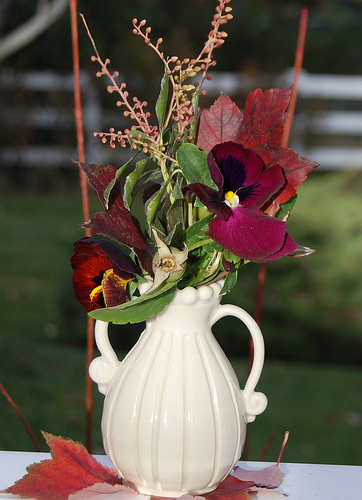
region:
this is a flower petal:
[29, 440, 97, 485]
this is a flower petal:
[237, 454, 300, 487]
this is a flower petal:
[81, 487, 124, 496]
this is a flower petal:
[218, 209, 288, 241]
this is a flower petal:
[206, 140, 261, 183]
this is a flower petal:
[251, 168, 288, 193]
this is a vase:
[93, 280, 260, 485]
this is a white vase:
[89, 282, 266, 493]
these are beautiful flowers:
[104, 113, 277, 286]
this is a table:
[4, 452, 13, 471]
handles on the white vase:
[81, 298, 279, 419]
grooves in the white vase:
[100, 325, 242, 487]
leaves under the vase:
[13, 434, 311, 498]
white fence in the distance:
[1, 65, 358, 196]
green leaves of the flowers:
[74, 71, 239, 321]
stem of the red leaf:
[274, 426, 292, 463]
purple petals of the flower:
[184, 138, 295, 260]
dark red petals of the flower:
[70, 231, 140, 308]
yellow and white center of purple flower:
[226, 190, 239, 207]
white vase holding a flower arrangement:
[68, 10, 297, 493]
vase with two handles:
[91, 284, 277, 493]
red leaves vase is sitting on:
[6, 424, 293, 499]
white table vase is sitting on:
[1, 447, 358, 499]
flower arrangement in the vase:
[60, 7, 323, 320]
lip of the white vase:
[133, 276, 222, 307]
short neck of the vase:
[138, 299, 216, 327]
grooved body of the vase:
[103, 325, 236, 494]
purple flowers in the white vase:
[186, 137, 299, 266]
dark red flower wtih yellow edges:
[64, 239, 131, 312]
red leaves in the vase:
[73, 88, 315, 269]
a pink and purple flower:
[188, 142, 287, 261]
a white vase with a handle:
[87, 279, 268, 491]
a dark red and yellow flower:
[70, 236, 135, 315]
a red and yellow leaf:
[7, 432, 130, 499]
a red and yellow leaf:
[193, 432, 296, 497]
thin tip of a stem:
[79, 12, 103, 56]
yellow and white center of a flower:
[224, 191, 238, 209]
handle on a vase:
[210, 304, 267, 421]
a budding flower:
[146, 227, 191, 291]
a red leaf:
[202, 90, 240, 151]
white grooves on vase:
[154, 421, 189, 444]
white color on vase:
[133, 398, 194, 436]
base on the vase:
[137, 484, 211, 496]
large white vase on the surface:
[78, 278, 281, 464]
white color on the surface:
[298, 470, 336, 491]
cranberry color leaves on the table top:
[37, 434, 80, 478]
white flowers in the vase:
[144, 249, 188, 282]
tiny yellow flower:
[222, 189, 242, 200]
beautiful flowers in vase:
[61, 95, 308, 323]